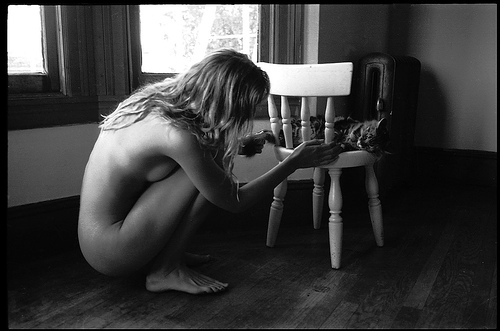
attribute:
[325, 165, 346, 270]
leg — spindled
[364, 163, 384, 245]
leg — spindled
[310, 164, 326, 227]
leg — spindled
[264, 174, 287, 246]
leg — spindled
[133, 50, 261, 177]
hair — messy, blonde, long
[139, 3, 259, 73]
window — open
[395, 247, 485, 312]
floor — wooden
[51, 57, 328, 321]
woman — nude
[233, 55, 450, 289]
chair — small, white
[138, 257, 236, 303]
foot — bare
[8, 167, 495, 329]
wood floor — brown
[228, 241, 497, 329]
floor — wooden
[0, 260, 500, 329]
brown floor — wood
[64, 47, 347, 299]
woman — holding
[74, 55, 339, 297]
lady — nude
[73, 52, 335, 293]
woman — naked, nude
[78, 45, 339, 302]
naked woman — nude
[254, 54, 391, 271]
chair — small, white, wooden, wood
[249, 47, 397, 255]
chair — wooden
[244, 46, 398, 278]
chair — white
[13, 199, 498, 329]
floor — wood, brown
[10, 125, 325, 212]
wall — white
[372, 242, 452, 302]
floor — wood, brown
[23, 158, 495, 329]
floor — brown, wood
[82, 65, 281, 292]
woman — naked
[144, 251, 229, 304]
foot — bare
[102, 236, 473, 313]
floor — wood, brown